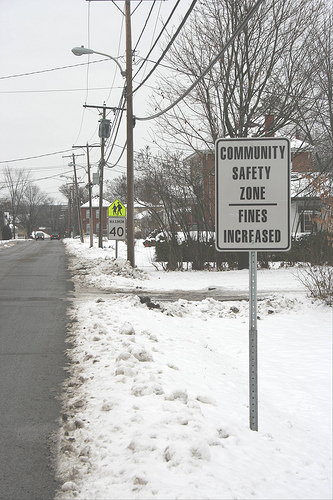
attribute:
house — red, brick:
[80, 199, 111, 238]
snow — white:
[198, 474, 217, 487]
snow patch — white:
[75, 297, 329, 498]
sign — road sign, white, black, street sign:
[213, 137, 291, 253]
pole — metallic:
[247, 250, 257, 430]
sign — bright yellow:
[104, 199, 127, 218]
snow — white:
[182, 330, 210, 375]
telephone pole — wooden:
[78, 138, 96, 253]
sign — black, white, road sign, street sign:
[106, 216, 125, 240]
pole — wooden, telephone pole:
[106, 33, 149, 299]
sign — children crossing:
[107, 195, 126, 216]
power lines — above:
[93, 0, 262, 64]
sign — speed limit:
[105, 215, 127, 245]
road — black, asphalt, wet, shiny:
[2, 235, 74, 497]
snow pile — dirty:
[88, 254, 152, 283]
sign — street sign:
[103, 214, 127, 239]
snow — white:
[78, 304, 331, 494]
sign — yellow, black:
[104, 196, 127, 217]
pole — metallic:
[204, 135, 295, 456]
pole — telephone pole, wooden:
[91, 117, 146, 243]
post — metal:
[242, 236, 270, 430]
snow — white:
[47, 295, 331, 498]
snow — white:
[60, 232, 332, 296]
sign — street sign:
[106, 197, 125, 216]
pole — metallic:
[244, 252, 259, 434]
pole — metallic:
[112, 240, 120, 259]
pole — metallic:
[122, 72, 141, 267]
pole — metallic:
[74, 157, 84, 242]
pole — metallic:
[85, 144, 96, 245]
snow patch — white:
[283, 429, 319, 474]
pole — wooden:
[76, 131, 148, 248]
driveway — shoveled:
[72, 283, 332, 307]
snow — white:
[115, 454, 127, 474]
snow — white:
[303, 359, 326, 386]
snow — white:
[150, 424, 205, 474]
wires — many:
[74, 7, 253, 182]